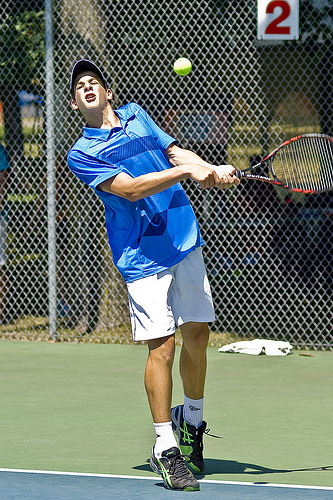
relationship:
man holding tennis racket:
[50, 59, 227, 354] [239, 143, 316, 198]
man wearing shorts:
[50, 59, 227, 354] [139, 288, 210, 333]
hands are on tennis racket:
[184, 161, 239, 186] [239, 143, 316, 198]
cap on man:
[69, 59, 90, 73] [50, 59, 227, 354]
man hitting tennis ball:
[50, 59, 227, 354] [162, 57, 200, 78]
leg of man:
[132, 358, 179, 411] [50, 59, 227, 354]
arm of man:
[108, 172, 180, 195] [50, 59, 227, 354]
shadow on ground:
[209, 460, 244, 479] [24, 453, 91, 486]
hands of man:
[184, 161, 239, 186] [50, 59, 227, 354]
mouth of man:
[82, 92, 96, 104] [50, 59, 227, 354]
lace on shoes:
[171, 462, 187, 473] [176, 413, 198, 475]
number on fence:
[244, 0, 302, 47] [152, 12, 203, 28]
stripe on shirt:
[106, 136, 150, 158] [138, 162, 152, 172]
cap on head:
[69, 59, 90, 73] [49, 78, 104, 121]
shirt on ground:
[138, 162, 152, 172] [24, 453, 91, 486]